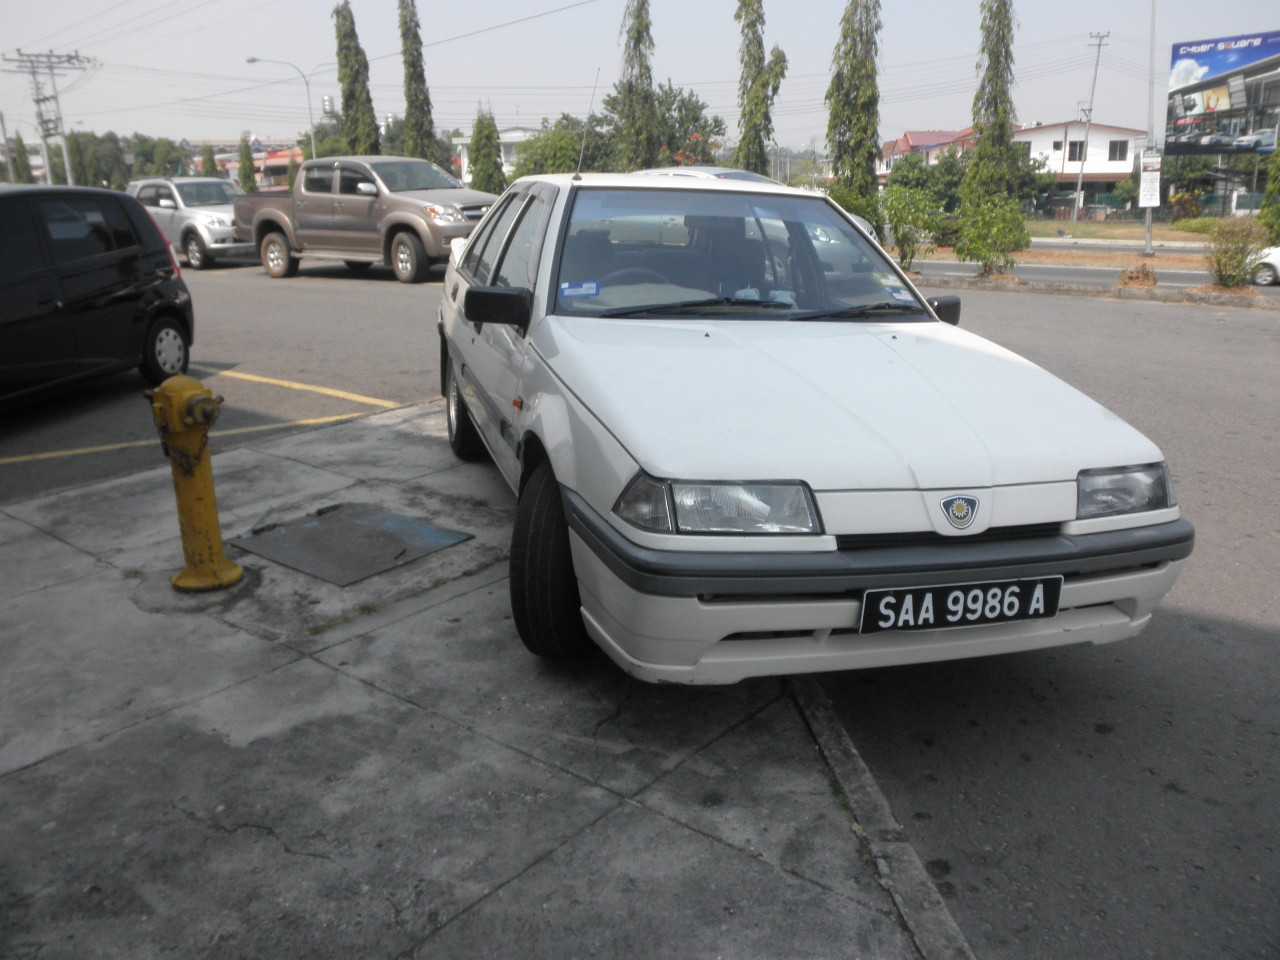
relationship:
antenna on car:
[569, 87, 603, 182] [439, 159, 1200, 717]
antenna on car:
[570, 68, 602, 181] [439, 159, 1200, 717]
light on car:
[609, 466, 823, 535] [439, 159, 1200, 717]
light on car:
[1060, 453, 1185, 525] [439, 159, 1200, 717]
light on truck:
[432, 203, 464, 228] [232, 154, 502, 283]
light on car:
[206, 208, 243, 231] [127, 176, 248, 269]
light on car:
[167, 250, 185, 284] [11, 185, 206, 422]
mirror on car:
[467, 283, 536, 336] [439, 159, 1200, 717]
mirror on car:
[928, 292, 958, 319] [439, 159, 1200, 717]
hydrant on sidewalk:
[146, 369, 253, 601] [8, 380, 978, 954]